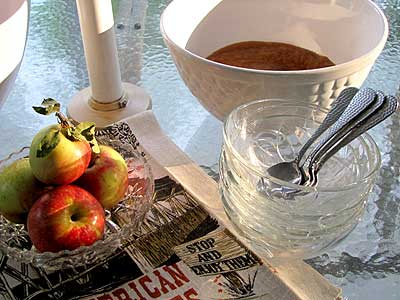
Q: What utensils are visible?
A: Spoons.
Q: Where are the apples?
A: In bowl.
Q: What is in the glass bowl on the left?
A: Apples.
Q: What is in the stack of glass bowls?
A: Spoons.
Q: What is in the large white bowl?
A: Cinnamon.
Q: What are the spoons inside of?
A: Small glass bowl.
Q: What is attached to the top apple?
A: Leaves.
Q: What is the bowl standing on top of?
A: Newspaper.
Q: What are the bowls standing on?
A: Table.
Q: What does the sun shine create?
A: Shadows.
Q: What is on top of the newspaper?
A: Bowl of apples.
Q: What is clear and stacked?
A: Bowls.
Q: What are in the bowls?
A: Spoons.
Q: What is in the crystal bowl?
A: Apples.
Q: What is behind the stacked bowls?
A: A big white bowl.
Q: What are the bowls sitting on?
A: A glass table.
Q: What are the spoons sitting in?
A: A bowl.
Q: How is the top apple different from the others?
A: It still has leaves.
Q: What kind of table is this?
A: A glass topped table.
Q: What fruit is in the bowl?
A: Apples.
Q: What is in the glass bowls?
A: Spoons.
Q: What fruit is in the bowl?
A: Apples.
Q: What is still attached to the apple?
A: The leaves.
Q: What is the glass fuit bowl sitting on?
A: A placemat.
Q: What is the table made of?
A: Glass.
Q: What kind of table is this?
A: An outdoor table.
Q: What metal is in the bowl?
A: Silver spoon.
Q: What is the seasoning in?
A: A white bowl.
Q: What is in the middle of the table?
A: A rod.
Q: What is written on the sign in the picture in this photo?
A: Stop and enjoy them.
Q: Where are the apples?
A: In a bowl.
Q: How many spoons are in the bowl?
A: Four.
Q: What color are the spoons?
A: Silver.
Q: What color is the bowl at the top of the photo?
A: White.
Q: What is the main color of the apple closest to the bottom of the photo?
A: Red.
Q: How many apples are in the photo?
A: Four.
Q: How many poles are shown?
A: One.